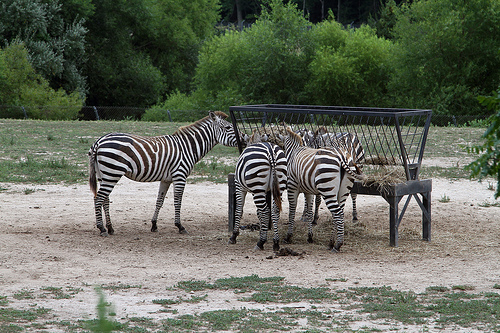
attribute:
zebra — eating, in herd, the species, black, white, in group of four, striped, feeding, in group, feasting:
[78, 110, 253, 240]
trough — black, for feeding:
[227, 99, 439, 258]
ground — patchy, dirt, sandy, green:
[4, 121, 500, 333]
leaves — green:
[458, 84, 499, 199]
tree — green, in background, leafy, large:
[0, 38, 90, 122]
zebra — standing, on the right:
[272, 127, 373, 252]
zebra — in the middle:
[227, 128, 292, 255]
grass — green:
[168, 276, 215, 295]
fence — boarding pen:
[72, 102, 152, 122]